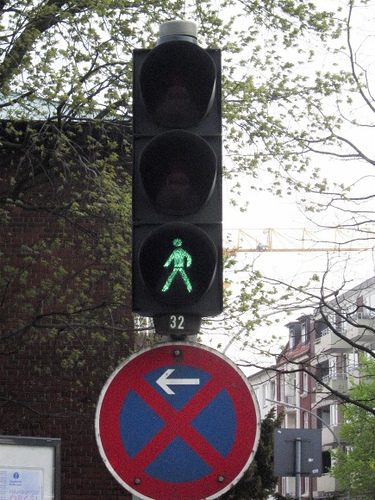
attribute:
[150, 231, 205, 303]
light — green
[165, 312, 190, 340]
number — 32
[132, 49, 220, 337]
base — black, tall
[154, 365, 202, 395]
arrow — white, small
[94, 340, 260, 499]
sign — round, blue, red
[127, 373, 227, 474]
x — red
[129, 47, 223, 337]
light — black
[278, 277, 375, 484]
building — tall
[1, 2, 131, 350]
tree — green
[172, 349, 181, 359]
screw — black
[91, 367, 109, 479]
edge — round, white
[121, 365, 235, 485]
circle — blue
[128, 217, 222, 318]
signal — green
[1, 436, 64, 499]
sign — white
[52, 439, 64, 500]
edge — grey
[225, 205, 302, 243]
sky — clear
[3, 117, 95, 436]
building — red, large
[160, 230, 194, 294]
person — green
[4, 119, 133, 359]
wall — brick